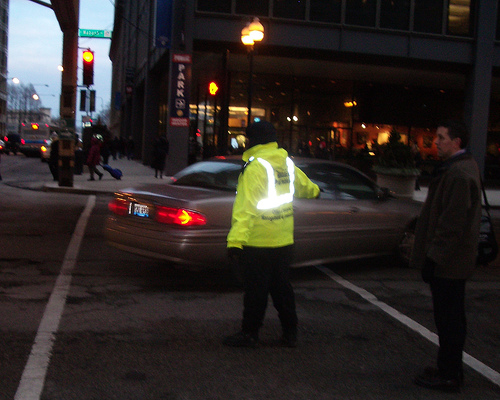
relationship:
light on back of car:
[156, 204, 206, 227] [103, 151, 420, 287]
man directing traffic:
[221, 120, 324, 349] [10, 113, 457, 303]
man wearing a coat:
[221, 120, 324, 349] [400, 151, 490, 291]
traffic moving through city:
[2, 119, 57, 160] [4, 6, 470, 181]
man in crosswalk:
[221, 120, 324, 349] [110, 184, 373, 394]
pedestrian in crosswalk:
[415, 124, 485, 390] [110, 184, 373, 394]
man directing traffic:
[221, 120, 324, 349] [123, 125, 427, 267]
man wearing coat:
[221, 120, 324, 349] [229, 147, 321, 256]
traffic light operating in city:
[71, 39, 131, 94] [54, 50, 413, 315]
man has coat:
[221, 120, 324, 349] [225, 142, 320, 248]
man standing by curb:
[221, 120, 324, 349] [387, 359, 484, 392]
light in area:
[233, 10, 297, 52] [7, 8, 477, 383]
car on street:
[103, 134, 447, 289] [47, 190, 484, 377]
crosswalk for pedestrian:
[21, 184, 485, 397] [415, 124, 485, 390]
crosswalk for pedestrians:
[21, 184, 485, 397] [49, 125, 188, 182]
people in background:
[47, 120, 117, 182] [20, 110, 477, 185]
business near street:
[108, 0, 499, 188] [0, 145, 500, 399]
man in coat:
[221, 113, 347, 353] [225, 141, 321, 257]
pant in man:
[217, 235, 319, 339] [219, 119, 322, 345]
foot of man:
[232, 311, 271, 343] [235, 112, 315, 336]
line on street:
[11, 189, 100, 397] [0, 183, 498, 398]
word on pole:
[177, 62, 187, 107] [171, 51, 197, 138]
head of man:
[419, 116, 459, 158] [226, 112, 336, 354]